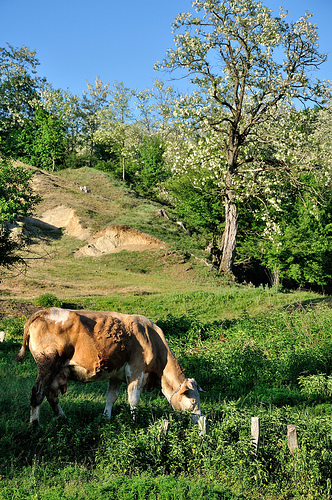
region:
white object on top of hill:
[69, 178, 89, 194]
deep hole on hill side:
[72, 227, 173, 259]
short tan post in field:
[239, 405, 276, 443]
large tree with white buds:
[181, 15, 283, 277]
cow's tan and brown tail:
[10, 321, 40, 362]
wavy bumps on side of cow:
[90, 310, 126, 349]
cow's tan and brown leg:
[99, 363, 149, 427]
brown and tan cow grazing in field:
[13, 310, 218, 435]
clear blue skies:
[25, 4, 152, 49]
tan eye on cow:
[184, 394, 199, 405]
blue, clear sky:
[22, 3, 143, 44]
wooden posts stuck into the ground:
[193, 405, 301, 447]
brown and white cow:
[13, 302, 202, 420]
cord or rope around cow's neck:
[166, 370, 186, 399]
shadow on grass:
[4, 399, 100, 465]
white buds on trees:
[162, 0, 322, 207]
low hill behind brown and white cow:
[1, 159, 231, 284]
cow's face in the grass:
[174, 378, 213, 429]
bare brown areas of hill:
[42, 205, 164, 251]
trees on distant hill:
[3, 73, 186, 185]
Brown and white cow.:
[13, 296, 220, 448]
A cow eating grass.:
[15, 300, 221, 451]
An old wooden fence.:
[138, 407, 321, 466]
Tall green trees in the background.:
[149, 49, 325, 300]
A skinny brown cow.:
[13, 296, 211, 455]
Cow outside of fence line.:
[9, 301, 256, 461]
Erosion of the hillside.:
[6, 154, 223, 324]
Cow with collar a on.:
[12, 285, 238, 494]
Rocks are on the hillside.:
[68, 175, 99, 196]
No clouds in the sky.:
[1, 3, 224, 85]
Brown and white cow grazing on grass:
[18, 305, 206, 429]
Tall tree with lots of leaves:
[156, 1, 308, 282]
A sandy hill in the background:
[0, 159, 226, 289]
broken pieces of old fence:
[196, 411, 297, 453]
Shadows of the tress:
[2, 207, 63, 259]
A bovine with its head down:
[14, 304, 206, 428]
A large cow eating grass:
[16, 307, 207, 430]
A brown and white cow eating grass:
[15, 306, 201, 429]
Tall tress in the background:
[1, 46, 196, 183]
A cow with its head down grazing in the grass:
[11, 301, 201, 426]